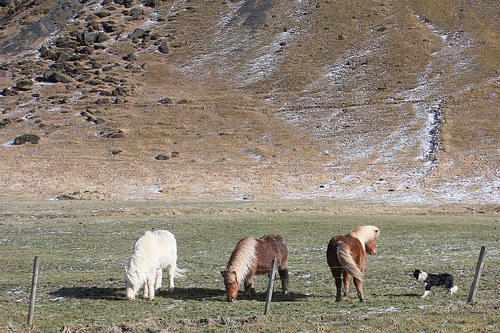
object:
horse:
[326, 225, 378, 301]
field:
[3, 214, 499, 333]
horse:
[220, 236, 289, 299]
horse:
[126, 230, 179, 300]